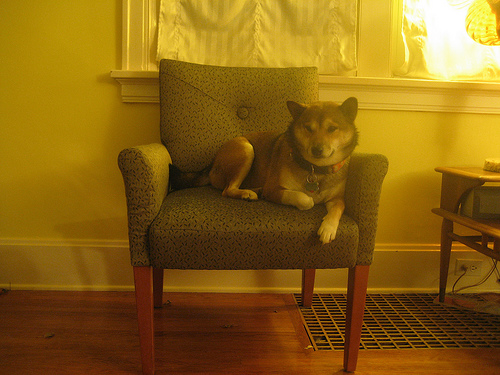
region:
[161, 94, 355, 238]
shibu inu dog sits in chair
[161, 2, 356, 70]
pale striped window coverings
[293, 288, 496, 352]
large floor air grate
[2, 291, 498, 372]
hardwood plank flooring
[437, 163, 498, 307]
midcentury style side table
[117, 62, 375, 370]
midcentury upholstered chair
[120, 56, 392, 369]
dog seated on one side of upholstered chair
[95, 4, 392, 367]
chair below fabric-covered window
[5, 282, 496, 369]
metal grating set into wooden floor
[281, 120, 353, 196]
dog wearing wide collar with hanging tags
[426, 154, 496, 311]
wooden table with shelf and spindly leg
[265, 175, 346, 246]
one paw curled under and the other hanging off chair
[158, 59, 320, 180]
fabric-covered button on back of chair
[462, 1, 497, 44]
yellow and glass lamp shade with dark swirls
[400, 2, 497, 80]
bright light shining through curtained window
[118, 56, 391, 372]
A dog sitting in a chair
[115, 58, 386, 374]
A chair with patterned cushions and wooden legs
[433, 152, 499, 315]
An end table standing against a wall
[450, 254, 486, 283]
An electric outlet with something plugged in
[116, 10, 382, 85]
The curtain on the window has light striped pattern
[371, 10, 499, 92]
Sunlight is coming through this window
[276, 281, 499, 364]
A heating vent in the floor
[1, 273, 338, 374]
A wood floor with debris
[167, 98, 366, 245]
A lounging dog with a collar on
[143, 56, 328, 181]
The back of a chair with a button in the center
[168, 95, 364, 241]
A contented dog with collar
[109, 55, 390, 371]
a dog resting on a chair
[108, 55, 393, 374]
a neoclassical chair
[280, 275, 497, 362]
an furnace return grate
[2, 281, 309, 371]
a wood floor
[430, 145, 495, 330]
part of a 50's style side table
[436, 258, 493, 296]
a power receptacle with cord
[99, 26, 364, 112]
a window wit closed blinds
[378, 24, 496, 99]
a window with open blinds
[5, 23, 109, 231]
a plain plaster wall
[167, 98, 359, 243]
a multicolored dog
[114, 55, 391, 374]
a chair with a dog in it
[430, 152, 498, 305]
wood end table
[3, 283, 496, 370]
floor made of wood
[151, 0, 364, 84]
striped white curtains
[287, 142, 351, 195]
dog's collar with identification tag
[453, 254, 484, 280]
a two plug outlet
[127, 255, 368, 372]
wood legs of a chair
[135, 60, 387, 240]
a big dog sitting in a chair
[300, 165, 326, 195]
several tags on a dog collar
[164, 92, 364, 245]
Shiba inu sitting on the sofa chair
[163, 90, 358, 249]
dog is laying in a chair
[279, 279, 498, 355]
vent in the floor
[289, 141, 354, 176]
dog is wearing a collar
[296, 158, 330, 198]
tags on the collar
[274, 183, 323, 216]
dog's paw is bent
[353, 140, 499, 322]
table next to the chair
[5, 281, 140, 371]
floors are wood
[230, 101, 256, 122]
button on the chair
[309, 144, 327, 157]
dog's nose is black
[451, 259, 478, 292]
cord plugged into outlet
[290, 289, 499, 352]
grate for a cold air return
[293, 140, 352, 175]
red and black dog collar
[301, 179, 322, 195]
a bone shaped dog tag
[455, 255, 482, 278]
plug in an electric outlet